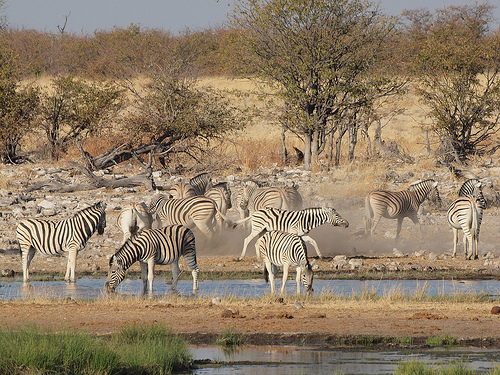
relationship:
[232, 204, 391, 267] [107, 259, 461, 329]
zebra next to a watering hole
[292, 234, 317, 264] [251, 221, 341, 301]
mane on a zebra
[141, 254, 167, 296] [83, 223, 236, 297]
leg on a zebra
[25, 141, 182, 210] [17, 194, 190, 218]
tree on ground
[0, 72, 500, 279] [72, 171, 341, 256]
ground behind zebras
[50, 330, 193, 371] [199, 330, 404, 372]
grass beside stream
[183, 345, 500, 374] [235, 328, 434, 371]
ripples on surface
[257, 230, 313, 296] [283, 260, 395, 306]
zebra drinking from stream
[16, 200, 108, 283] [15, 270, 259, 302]
zebra standing in stream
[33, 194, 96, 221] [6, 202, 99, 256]
rocks covering ground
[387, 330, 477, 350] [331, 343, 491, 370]
grass growing on stream shore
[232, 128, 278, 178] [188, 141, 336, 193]
grass growing in field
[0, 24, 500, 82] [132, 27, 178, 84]
trees with leaves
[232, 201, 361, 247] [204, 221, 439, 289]
zebra running down shore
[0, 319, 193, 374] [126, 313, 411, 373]
grass growing beside pond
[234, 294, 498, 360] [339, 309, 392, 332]
ground covered in dirt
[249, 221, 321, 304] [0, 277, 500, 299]
zebra drinking from stream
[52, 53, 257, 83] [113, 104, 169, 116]
trees covered in green leaves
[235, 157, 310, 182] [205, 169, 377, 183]
ground covered in large rocks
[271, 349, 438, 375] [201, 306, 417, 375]
ripples on pond water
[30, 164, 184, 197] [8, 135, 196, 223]
log laying on ground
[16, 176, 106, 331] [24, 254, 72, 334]
zebra standing in water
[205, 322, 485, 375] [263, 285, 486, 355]
muddy water near a watering hole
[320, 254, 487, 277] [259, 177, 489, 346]
rocks alongside watering hole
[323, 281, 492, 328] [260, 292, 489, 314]
grass by watering hole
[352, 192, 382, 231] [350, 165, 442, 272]
tail on a giraffe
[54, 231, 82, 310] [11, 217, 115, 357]
two white front legs on a zebra